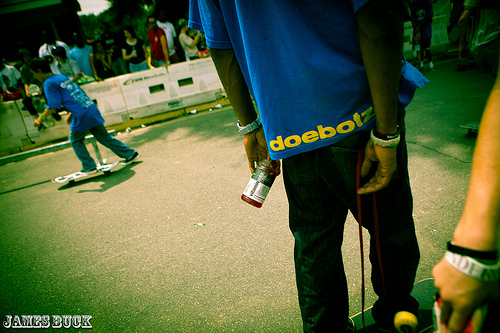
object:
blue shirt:
[187, 0, 429, 160]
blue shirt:
[43, 74, 106, 132]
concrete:
[217, 274, 280, 309]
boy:
[31, 60, 139, 175]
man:
[66, 31, 101, 85]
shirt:
[68, 45, 97, 78]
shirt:
[146, 28, 171, 63]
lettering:
[464, 262, 497, 282]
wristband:
[440, 241, 499, 283]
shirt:
[121, 38, 146, 64]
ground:
[445, 135, 469, 160]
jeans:
[282, 110, 422, 333]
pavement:
[0, 180, 58, 221]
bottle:
[239, 147, 280, 208]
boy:
[187, 1, 427, 333]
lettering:
[269, 107, 378, 152]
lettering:
[60, 79, 93, 110]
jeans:
[67, 114, 140, 172]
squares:
[96, 191, 265, 250]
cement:
[35, 187, 137, 253]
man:
[145, 19, 168, 72]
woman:
[122, 27, 146, 74]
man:
[39, 32, 69, 64]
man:
[155, 13, 179, 64]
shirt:
[36, 40, 67, 75]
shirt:
[154, 20, 178, 55]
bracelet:
[236, 117, 262, 134]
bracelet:
[370, 124, 400, 148]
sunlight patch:
[31, 125, 471, 328]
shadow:
[72, 157, 140, 193]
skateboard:
[51, 161, 120, 185]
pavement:
[419, 151, 465, 200]